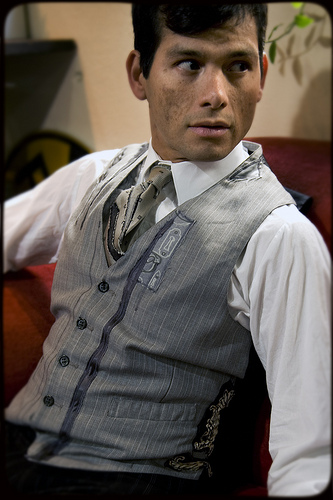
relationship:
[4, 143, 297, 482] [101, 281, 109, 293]
vest with button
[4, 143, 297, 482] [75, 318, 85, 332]
vest with button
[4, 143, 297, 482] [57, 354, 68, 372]
vest with button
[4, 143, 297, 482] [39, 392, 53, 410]
vest with button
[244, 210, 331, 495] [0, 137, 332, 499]
sleeve of shirt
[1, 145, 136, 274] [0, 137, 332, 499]
sleeve of shirt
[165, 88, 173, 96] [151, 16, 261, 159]
blemish on face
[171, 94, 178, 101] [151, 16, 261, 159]
blemish on face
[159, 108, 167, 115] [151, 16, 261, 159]
blemish on face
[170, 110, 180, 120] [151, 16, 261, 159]
blemish on face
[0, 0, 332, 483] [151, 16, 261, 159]
man has face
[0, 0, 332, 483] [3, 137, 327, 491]
man on furniture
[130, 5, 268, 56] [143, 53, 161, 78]
hair with sideburn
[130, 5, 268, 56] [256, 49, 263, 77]
hair with sideburn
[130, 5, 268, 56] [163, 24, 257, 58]
hair on brow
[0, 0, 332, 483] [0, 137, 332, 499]
man wearing shirt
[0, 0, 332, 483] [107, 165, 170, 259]
man wearing tie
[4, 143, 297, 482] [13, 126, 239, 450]
vest with front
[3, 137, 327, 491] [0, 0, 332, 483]
furniture enveloping man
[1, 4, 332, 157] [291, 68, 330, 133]
wall with shadow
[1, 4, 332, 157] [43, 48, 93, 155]
wall with shadow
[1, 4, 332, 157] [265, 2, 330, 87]
wall with plant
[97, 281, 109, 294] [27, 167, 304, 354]
button on the vest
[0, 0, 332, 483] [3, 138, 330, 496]
man wearing t shirt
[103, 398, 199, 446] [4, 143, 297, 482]
pocket on vest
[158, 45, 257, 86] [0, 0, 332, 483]
eyes of a man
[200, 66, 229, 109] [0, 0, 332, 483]
nose of a man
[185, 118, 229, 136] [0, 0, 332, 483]
mouth of a man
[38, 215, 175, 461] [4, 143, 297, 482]
line on vest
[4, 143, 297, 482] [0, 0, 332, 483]
vest on man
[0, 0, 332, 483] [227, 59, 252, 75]
man has eyes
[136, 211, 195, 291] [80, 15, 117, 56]
patch on vest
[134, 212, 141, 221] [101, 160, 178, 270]
squares on tie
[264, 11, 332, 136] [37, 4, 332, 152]
shadow on wall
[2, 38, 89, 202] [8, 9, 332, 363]
furniture in room